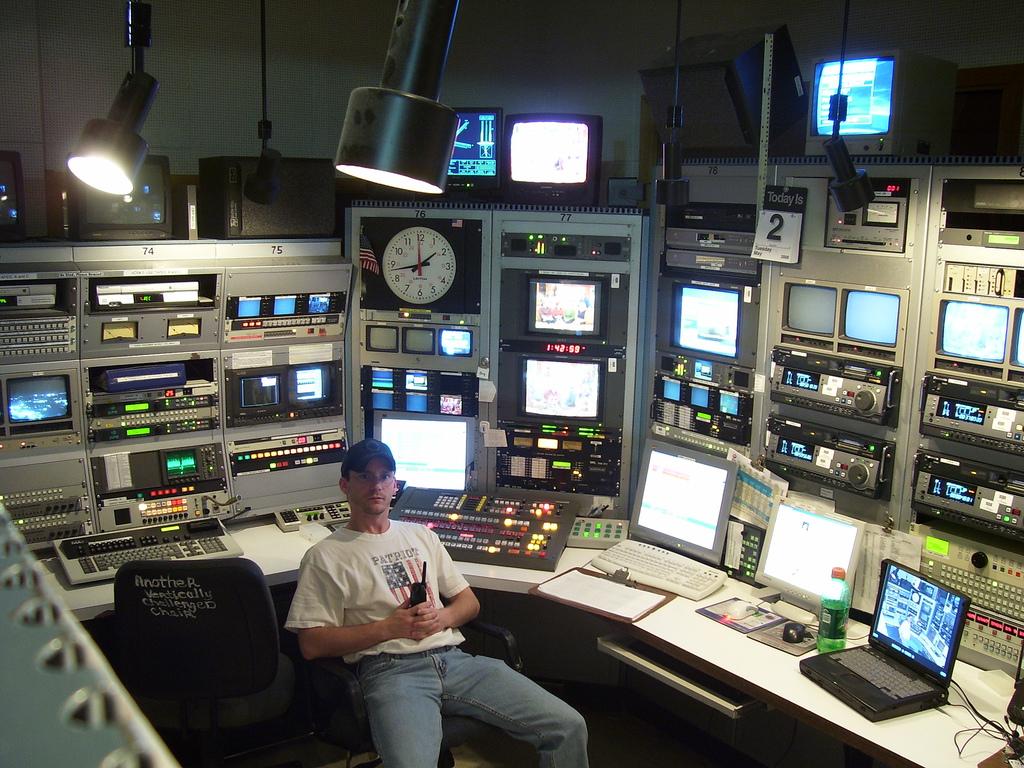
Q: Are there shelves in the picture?
A: No, there are no shelves.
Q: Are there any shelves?
A: No, there are no shelves.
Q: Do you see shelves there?
A: No, there are no shelves.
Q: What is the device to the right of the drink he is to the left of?
A: The device is a monitor.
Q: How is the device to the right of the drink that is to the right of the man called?
A: The device is a monitor.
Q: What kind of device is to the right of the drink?
A: The device is a monitor.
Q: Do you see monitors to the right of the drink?
A: Yes, there is a monitor to the right of the drink.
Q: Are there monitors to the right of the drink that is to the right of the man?
A: Yes, there is a monitor to the right of the drink.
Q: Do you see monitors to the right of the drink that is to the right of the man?
A: Yes, there is a monitor to the right of the drink.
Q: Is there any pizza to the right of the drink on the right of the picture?
A: No, there is a monitor to the right of the drink.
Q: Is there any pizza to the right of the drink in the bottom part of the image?
A: No, there is a monitor to the right of the drink.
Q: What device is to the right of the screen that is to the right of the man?
A: The device is a monitor.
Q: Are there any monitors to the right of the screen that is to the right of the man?
A: Yes, there is a monitor to the right of the screen.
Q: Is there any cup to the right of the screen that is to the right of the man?
A: No, there is a monitor to the right of the screen.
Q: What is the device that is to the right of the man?
A: The device is a monitor.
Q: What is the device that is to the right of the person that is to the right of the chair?
A: The device is a monitor.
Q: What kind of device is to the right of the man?
A: The device is a monitor.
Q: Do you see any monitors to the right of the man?
A: Yes, there is a monitor to the right of the man.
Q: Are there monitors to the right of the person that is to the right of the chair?
A: Yes, there is a monitor to the right of the man.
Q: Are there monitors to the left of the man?
A: No, the monitor is to the right of the man.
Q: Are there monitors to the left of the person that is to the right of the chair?
A: No, the monitor is to the right of the man.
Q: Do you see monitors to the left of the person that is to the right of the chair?
A: No, the monitor is to the right of the man.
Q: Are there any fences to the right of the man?
A: No, there is a monitor to the right of the man.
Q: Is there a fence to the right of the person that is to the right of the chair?
A: No, there is a monitor to the right of the man.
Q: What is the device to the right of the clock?
A: The device is a monitor.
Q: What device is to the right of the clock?
A: The device is a monitor.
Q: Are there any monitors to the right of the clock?
A: Yes, there is a monitor to the right of the clock.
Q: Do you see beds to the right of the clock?
A: No, there is a monitor to the right of the clock.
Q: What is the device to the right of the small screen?
A: The device is a monitor.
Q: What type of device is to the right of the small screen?
A: The device is a monitor.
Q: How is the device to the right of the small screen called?
A: The device is a monitor.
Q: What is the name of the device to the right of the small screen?
A: The device is a monitor.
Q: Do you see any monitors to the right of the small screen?
A: Yes, there is a monitor to the right of the screen.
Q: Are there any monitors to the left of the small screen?
A: No, the monitor is to the right of the screen.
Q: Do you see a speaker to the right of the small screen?
A: No, there is a monitor to the right of the screen.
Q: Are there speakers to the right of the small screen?
A: No, there is a monitor to the right of the screen.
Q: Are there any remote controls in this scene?
A: No, there are no remote controls.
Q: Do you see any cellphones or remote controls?
A: No, there are no remote controls or cellphones.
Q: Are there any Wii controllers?
A: No, there are no Wii controllers.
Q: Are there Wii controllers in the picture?
A: No, there are no Wii controllers.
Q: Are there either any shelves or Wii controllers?
A: No, there are no Wii controllers or shelves.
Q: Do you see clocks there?
A: Yes, there is a clock.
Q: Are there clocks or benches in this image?
A: Yes, there is a clock.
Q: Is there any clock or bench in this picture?
A: Yes, there is a clock.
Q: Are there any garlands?
A: No, there are no garlands.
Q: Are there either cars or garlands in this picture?
A: No, there are no garlands or cars.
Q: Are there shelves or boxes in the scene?
A: No, there are no shelves or boxes.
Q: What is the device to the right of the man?
A: The device is a screen.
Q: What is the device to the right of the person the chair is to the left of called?
A: The device is a screen.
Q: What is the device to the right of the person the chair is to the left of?
A: The device is a screen.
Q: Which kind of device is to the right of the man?
A: The device is a screen.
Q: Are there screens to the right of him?
A: Yes, there is a screen to the right of the man.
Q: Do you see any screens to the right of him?
A: Yes, there is a screen to the right of the man.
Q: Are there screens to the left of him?
A: No, the screen is to the right of the man.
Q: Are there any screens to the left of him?
A: No, the screen is to the right of the man.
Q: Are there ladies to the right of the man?
A: No, there is a screen to the right of the man.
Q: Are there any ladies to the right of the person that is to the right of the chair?
A: No, there is a screen to the right of the man.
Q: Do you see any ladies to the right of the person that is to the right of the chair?
A: No, there is a screen to the right of the man.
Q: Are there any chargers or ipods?
A: No, there are no ipods or chargers.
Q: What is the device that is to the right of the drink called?
A: The device is a screen.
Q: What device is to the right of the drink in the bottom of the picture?
A: The device is a screen.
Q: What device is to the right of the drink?
A: The device is a screen.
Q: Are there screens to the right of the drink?
A: Yes, there is a screen to the right of the drink.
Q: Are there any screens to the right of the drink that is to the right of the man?
A: Yes, there is a screen to the right of the drink.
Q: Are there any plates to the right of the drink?
A: No, there is a screen to the right of the drink.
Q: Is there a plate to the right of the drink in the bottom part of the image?
A: No, there is a screen to the right of the drink.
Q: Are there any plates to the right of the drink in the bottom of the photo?
A: No, there is a screen to the right of the drink.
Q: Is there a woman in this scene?
A: No, there are no women.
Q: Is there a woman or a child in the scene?
A: No, there are no women or children.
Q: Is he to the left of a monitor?
A: Yes, the man is to the left of a monitor.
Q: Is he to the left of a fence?
A: No, the man is to the left of a monitor.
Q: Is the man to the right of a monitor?
A: No, the man is to the left of a monitor.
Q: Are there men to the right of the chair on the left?
A: Yes, there is a man to the right of the chair.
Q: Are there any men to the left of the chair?
A: No, the man is to the right of the chair.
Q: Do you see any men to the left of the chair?
A: No, the man is to the right of the chair.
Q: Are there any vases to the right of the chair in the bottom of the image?
A: No, there is a man to the right of the chair.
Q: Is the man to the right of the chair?
A: Yes, the man is to the right of the chair.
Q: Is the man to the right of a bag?
A: No, the man is to the right of the chair.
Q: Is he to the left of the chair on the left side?
A: No, the man is to the right of the chair.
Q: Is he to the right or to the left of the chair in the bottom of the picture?
A: The man is to the right of the chair.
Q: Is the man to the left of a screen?
A: Yes, the man is to the left of a screen.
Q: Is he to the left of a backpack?
A: No, the man is to the left of a screen.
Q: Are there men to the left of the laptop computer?
A: Yes, there is a man to the left of the laptop computer.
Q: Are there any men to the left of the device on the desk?
A: Yes, there is a man to the left of the laptop computer.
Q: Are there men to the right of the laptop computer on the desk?
A: No, the man is to the left of the laptop.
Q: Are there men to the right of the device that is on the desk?
A: No, the man is to the left of the laptop.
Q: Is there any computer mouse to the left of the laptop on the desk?
A: No, there is a man to the left of the laptop computer.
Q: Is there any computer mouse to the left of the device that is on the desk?
A: No, there is a man to the left of the laptop computer.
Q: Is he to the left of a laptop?
A: Yes, the man is to the left of a laptop.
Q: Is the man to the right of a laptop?
A: No, the man is to the left of a laptop.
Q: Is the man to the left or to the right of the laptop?
A: The man is to the left of the laptop.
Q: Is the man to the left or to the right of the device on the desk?
A: The man is to the left of the laptop.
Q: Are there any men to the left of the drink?
A: Yes, there is a man to the left of the drink.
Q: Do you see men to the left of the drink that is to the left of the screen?
A: Yes, there is a man to the left of the drink.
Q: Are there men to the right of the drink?
A: No, the man is to the left of the drink.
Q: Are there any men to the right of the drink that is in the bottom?
A: No, the man is to the left of the drink.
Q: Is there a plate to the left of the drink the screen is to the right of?
A: No, there is a man to the left of the drink.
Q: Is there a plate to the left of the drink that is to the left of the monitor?
A: No, there is a man to the left of the drink.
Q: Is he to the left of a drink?
A: Yes, the man is to the left of a drink.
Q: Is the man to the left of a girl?
A: No, the man is to the left of a drink.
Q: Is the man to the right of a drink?
A: No, the man is to the left of a drink.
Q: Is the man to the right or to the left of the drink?
A: The man is to the left of the drink.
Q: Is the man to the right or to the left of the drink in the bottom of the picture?
A: The man is to the left of the drink.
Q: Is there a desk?
A: Yes, there is a desk.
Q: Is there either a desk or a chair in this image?
A: Yes, there is a desk.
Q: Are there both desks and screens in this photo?
A: Yes, there are both a desk and a screen.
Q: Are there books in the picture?
A: No, there are no books.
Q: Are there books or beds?
A: No, there are no books or beds.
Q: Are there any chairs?
A: Yes, there is a chair.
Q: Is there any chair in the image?
A: Yes, there is a chair.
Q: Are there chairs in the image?
A: Yes, there is a chair.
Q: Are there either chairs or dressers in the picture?
A: Yes, there is a chair.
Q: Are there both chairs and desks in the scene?
A: Yes, there are both a chair and a desk.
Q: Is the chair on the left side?
A: Yes, the chair is on the left of the image.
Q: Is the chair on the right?
A: No, the chair is on the left of the image.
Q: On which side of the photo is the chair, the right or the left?
A: The chair is on the left of the image.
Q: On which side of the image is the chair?
A: The chair is on the left of the image.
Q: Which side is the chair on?
A: The chair is on the left of the image.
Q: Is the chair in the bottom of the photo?
A: Yes, the chair is in the bottom of the image.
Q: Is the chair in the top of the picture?
A: No, the chair is in the bottom of the image.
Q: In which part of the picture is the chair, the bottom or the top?
A: The chair is in the bottom of the image.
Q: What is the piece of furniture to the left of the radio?
A: The piece of furniture is a chair.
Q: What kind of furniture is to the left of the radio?
A: The piece of furniture is a chair.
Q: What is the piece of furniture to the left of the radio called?
A: The piece of furniture is a chair.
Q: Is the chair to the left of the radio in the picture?
A: Yes, the chair is to the left of the radio.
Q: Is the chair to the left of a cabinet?
A: No, the chair is to the left of the radio.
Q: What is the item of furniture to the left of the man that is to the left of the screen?
A: The piece of furniture is a chair.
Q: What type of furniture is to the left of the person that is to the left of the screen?
A: The piece of furniture is a chair.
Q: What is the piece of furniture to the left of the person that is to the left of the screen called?
A: The piece of furniture is a chair.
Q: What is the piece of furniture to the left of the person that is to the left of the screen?
A: The piece of furniture is a chair.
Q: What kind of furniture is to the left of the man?
A: The piece of furniture is a chair.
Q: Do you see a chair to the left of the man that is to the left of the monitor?
A: Yes, there is a chair to the left of the man.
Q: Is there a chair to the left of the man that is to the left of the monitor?
A: Yes, there is a chair to the left of the man.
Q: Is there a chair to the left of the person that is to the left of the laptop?
A: Yes, there is a chair to the left of the man.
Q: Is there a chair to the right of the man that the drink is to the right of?
A: No, the chair is to the left of the man.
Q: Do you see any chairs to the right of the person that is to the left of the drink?
A: No, the chair is to the left of the man.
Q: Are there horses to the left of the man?
A: No, there is a chair to the left of the man.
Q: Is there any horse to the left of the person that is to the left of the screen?
A: No, there is a chair to the left of the man.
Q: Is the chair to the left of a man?
A: Yes, the chair is to the left of a man.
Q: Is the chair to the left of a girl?
A: No, the chair is to the left of a man.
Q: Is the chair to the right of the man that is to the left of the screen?
A: No, the chair is to the left of the man.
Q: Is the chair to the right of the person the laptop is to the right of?
A: No, the chair is to the left of the man.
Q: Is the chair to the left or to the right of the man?
A: The chair is to the left of the man.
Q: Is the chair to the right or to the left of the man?
A: The chair is to the left of the man.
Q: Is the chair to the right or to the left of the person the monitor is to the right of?
A: The chair is to the left of the man.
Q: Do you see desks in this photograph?
A: Yes, there is a desk.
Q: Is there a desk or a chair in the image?
A: Yes, there is a desk.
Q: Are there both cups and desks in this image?
A: No, there is a desk but no cups.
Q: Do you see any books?
A: No, there are no books.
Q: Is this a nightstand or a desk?
A: This is a desk.